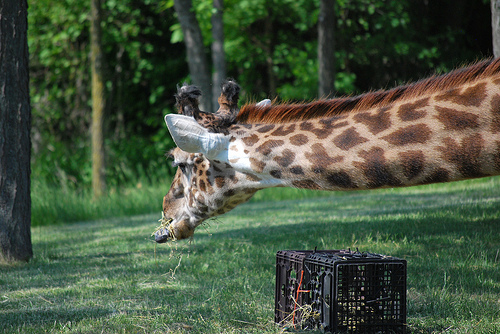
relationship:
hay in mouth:
[150, 211, 177, 243] [158, 214, 176, 234]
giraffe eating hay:
[148, 56, 491, 243] [150, 211, 177, 243]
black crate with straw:
[272, 245, 407, 331] [278, 304, 320, 327]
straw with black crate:
[273, 292, 325, 332] [272, 245, 407, 331]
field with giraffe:
[3, 174, 498, 332] [148, 56, 491, 243]